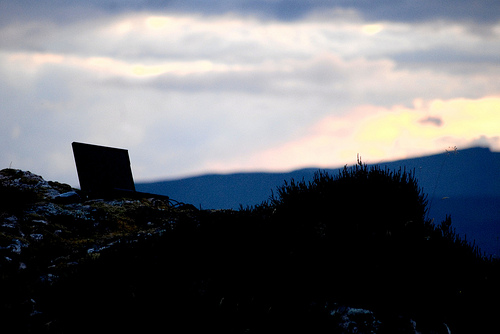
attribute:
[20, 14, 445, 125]
sky — purple, cloudy, blue, white, orange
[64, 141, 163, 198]
box — black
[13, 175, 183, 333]
hillside — rocky, bushy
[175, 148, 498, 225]
mountains — tall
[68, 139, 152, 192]
laptop — black, open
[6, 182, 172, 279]
rocks — dirty, white, gray